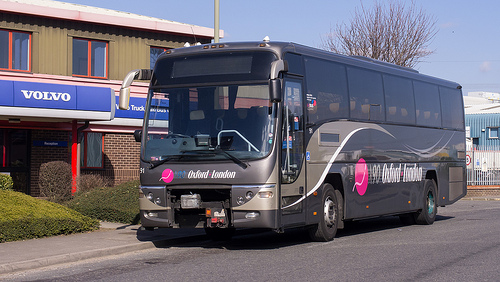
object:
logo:
[339, 157, 423, 197]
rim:
[324, 194, 338, 224]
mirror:
[116, 66, 152, 111]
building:
[0, 0, 225, 197]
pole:
[69, 134, 82, 200]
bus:
[117, 39, 469, 241]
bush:
[74, 174, 116, 228]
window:
[436, 78, 464, 133]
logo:
[352, 153, 373, 198]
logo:
[157, 164, 173, 185]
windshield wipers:
[149, 148, 254, 173]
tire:
[308, 181, 342, 243]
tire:
[413, 177, 441, 224]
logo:
[20, 85, 76, 104]